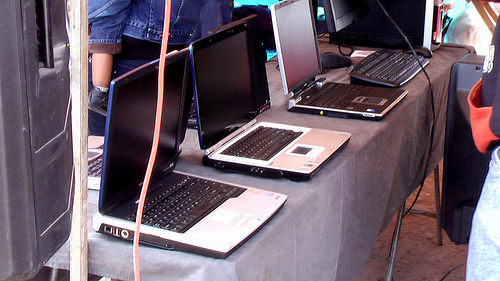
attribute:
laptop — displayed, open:
[89, 43, 292, 262]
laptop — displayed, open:
[184, 11, 356, 184]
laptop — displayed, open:
[265, 0, 414, 125]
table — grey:
[40, 23, 478, 280]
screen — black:
[103, 54, 187, 207]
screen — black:
[192, 18, 271, 146]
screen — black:
[275, 0, 321, 92]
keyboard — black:
[122, 172, 249, 236]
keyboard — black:
[217, 122, 307, 163]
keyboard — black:
[305, 79, 376, 112]